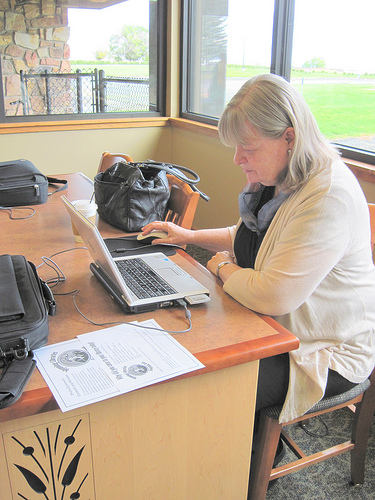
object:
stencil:
[10, 418, 88, 499]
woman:
[139, 73, 374, 405]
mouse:
[135, 227, 174, 247]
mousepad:
[101, 230, 177, 255]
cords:
[37, 243, 191, 333]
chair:
[237, 188, 374, 498]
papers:
[28, 316, 208, 412]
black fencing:
[18, 68, 153, 114]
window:
[0, 1, 151, 116]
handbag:
[84, 149, 212, 234]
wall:
[167, 124, 372, 266]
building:
[1, 1, 373, 499]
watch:
[216, 260, 234, 278]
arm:
[205, 195, 349, 315]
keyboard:
[112, 250, 199, 318]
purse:
[93, 161, 172, 231]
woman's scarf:
[233, 185, 291, 226]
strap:
[0, 355, 41, 408]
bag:
[0, 249, 61, 354]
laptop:
[34, 206, 250, 332]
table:
[178, 308, 276, 359]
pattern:
[3, 411, 97, 498]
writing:
[61, 364, 112, 398]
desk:
[1, 169, 304, 496]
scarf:
[233, 182, 288, 270]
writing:
[49, 345, 89, 371]